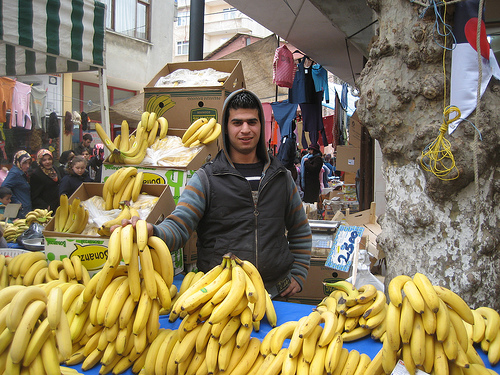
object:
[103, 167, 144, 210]
bananas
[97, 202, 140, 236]
bananas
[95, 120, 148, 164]
bananas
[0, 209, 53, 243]
bananas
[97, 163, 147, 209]
bananas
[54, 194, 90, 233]
bananas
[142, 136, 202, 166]
bananas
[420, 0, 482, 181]
cord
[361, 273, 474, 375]
bananas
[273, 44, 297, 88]
clothes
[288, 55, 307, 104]
clothes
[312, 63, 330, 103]
clothes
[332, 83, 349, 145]
clothes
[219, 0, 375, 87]
canopy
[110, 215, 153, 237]
hand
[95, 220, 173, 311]
banana bunch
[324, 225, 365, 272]
price tag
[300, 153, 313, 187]
scarf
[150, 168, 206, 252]
sleeves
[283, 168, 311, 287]
sleeves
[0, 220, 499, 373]
bananas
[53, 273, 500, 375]
cover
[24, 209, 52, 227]
banana bunch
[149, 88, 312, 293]
hoodie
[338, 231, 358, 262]
price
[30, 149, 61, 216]
woman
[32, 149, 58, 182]
scarf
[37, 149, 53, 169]
head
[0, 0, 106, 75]
awning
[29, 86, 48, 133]
clothes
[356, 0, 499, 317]
rock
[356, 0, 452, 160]
string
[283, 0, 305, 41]
line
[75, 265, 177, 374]
bananas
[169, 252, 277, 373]
banana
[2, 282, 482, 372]
table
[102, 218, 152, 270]
banana bunch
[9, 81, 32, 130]
clothes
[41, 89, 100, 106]
line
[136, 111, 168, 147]
bananas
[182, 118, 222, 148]
bananas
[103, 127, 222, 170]
box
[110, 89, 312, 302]
man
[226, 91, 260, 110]
hair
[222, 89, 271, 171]
hood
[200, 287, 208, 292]
sticker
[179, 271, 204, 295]
banana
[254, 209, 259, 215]
zipper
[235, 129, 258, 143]
smile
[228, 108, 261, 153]
face